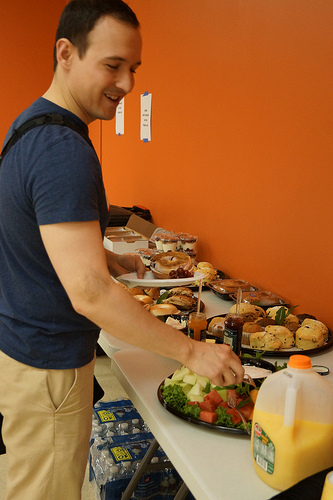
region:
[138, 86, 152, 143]
paper sign taped to wall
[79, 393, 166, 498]
bottled water under table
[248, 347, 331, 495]
gallon of orange juice on table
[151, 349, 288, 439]
tray of fresh fruit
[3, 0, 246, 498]
man selecting food for breakfast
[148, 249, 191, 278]
bagel on man's plate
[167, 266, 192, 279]
red grapes on man's plate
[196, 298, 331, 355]
tray of assorted pastries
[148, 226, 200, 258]
yogurt parfaits stacked on table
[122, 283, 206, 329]
tray of assorted bagels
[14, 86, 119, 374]
man's shirt is blue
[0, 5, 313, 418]
man is grabbing food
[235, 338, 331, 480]
jug of orange juice on table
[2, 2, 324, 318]
the wall is orange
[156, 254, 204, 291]
grapes on man's plate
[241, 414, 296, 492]
green sticker on the jug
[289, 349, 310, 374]
jug has orange top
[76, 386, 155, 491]
bottled water in packaging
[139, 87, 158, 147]
White sign taped to wall with blue tape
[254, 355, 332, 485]
Gallon jug of orange juice on table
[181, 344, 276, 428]
Person's hand above crudites platter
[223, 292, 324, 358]
Jam jar next to plate of scones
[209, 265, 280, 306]
Two covered plastic take-out containers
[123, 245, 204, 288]
Person holding a plate containing a bagel and grapes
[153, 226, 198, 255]
Four yogurt parfait cups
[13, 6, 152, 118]
Man smiling with closed eyes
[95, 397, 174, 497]
Two cases of water bottles under table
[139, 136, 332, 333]
Orange wall behind banquet table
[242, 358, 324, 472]
A gallon of orange juice on the counter.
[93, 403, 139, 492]
Packages of water on the floor.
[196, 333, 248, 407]
The hand in the fruit platter.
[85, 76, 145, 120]
The man is smiling.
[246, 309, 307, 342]
Breads on the platter.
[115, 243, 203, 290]
The man has a plate in his hand.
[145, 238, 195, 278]
A bagel and grapes on the plate.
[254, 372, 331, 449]
The juice jug is half way empty.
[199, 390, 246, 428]
Watermelon on the fruit platter.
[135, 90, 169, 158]
A sign on the orange wall.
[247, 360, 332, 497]
gallon of orange juice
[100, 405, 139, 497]
two cases of water under the table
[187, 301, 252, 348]
jellies opened with a spoon in each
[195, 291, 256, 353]
two jellies on the table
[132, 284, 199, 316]
bagels on a tray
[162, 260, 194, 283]
grapes on the plate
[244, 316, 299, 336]
muffins on a tray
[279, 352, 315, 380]
orange lid on orange juice jug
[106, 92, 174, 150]
two papers taped to the wall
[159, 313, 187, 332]
cream cheese on the table